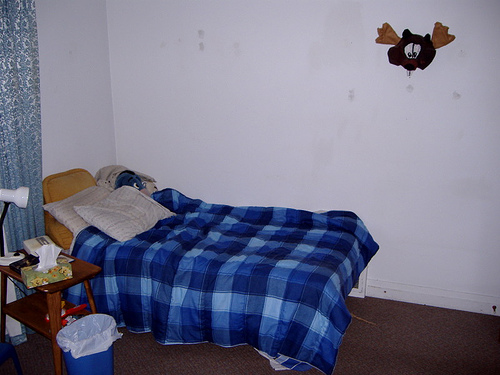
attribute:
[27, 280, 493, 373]
carpet — red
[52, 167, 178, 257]
bed pillow — white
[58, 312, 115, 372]
garbage can — blue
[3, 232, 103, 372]
table —  small and wooden 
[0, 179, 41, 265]
lamp — white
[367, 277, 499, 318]
trim — white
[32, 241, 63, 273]
tissue — facial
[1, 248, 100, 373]
table — small, wooden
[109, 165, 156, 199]
doll —  plush Eeyore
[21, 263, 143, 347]
table — brown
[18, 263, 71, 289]
tissue box — flowered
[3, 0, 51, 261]
curtain — hanging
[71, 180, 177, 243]
pillow — white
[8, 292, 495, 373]
brown carpet — brown 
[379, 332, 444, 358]
carpet —  dark brown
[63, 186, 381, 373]
comforter — checkered, blue, striped and blue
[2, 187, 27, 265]
lamp — white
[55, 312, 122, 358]
trash bag — white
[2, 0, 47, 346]
curtain — long, blue, white,  light blue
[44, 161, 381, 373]
twin bed — twin 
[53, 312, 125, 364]
trash can — blue,  lined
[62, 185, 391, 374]
spread — blue, checkered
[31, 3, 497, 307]
walls — white 